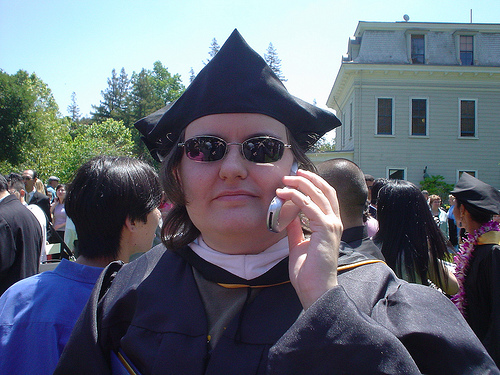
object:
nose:
[217, 143, 248, 183]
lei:
[453, 221, 498, 312]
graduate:
[444, 166, 499, 346]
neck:
[461, 217, 495, 248]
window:
[409, 95, 429, 137]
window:
[458, 99, 475, 136]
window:
[409, 34, 426, 64]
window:
[458, 32, 475, 65]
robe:
[53, 211, 493, 375]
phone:
[264, 161, 307, 236]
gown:
[52, 233, 496, 373]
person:
[52, 23, 500, 375]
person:
[4, 112, 201, 371]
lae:
[449, 220, 496, 304]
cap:
[130, 23, 342, 159]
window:
[368, 91, 400, 148]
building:
[314, 6, 499, 191]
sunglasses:
[181, 121, 286, 171]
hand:
[275, 167, 349, 297]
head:
[167, 112, 302, 251]